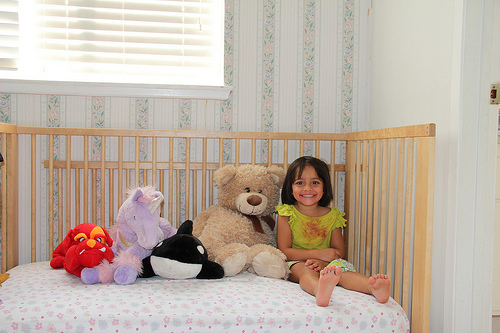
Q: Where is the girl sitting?
A: On a bed.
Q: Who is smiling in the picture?
A: The little girl.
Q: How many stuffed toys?
A: 4.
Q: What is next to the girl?
A: A big teddy bear.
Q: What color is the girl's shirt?
A: Lime green.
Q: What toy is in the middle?
A: A stuffed whale.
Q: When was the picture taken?
A: During daytime.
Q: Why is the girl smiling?
A: She is happy.